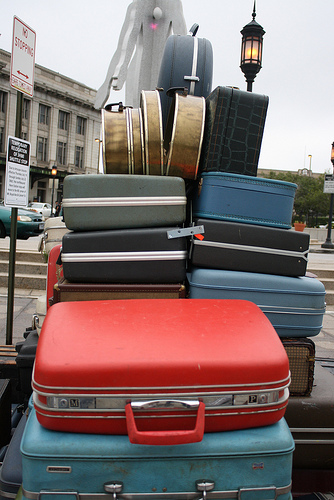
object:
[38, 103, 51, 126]
window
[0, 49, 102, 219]
building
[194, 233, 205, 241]
sticker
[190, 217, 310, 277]
suitcase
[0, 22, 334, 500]
large stack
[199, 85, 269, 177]
luggage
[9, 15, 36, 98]
sign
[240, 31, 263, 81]
lamp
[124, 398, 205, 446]
handle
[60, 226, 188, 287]
suitcase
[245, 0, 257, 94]
lamp post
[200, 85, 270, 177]
suitcase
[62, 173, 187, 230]
suitcase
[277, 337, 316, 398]
checkered suitcase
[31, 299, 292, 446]
suit case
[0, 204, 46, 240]
car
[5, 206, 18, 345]
pole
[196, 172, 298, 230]
blue suitcase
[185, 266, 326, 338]
blue suitcase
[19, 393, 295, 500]
blue suitcase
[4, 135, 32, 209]
sign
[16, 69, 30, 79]
arrow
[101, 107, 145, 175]
luggage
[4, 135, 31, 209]
white lettering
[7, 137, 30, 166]
black background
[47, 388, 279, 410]
accents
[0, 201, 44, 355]
street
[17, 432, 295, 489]
scruff marks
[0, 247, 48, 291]
steps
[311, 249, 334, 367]
street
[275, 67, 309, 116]
right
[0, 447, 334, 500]
foreground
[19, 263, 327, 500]
pile